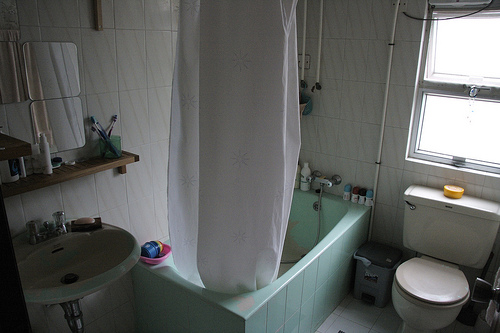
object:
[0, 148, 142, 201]
wood shelf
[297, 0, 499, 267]
wall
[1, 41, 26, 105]
squares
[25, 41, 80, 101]
squares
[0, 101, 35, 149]
squares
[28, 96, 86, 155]
squares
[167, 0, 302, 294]
shower curtain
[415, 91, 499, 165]
window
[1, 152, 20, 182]
toiletries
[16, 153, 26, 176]
toiletries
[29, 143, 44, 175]
toiletries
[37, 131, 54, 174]
toiletries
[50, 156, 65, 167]
toiletries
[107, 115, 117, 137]
toothbrush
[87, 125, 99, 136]
toothbrush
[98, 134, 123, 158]
glass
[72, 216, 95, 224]
soap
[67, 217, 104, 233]
dish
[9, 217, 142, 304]
sink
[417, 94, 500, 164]
light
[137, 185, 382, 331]
tub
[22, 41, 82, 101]
bathroom mirror